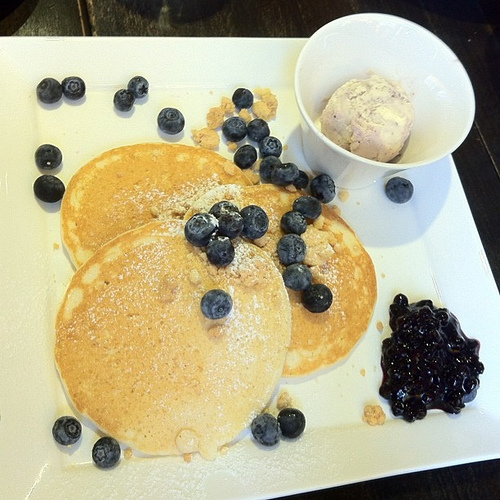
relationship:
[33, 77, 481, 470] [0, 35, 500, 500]
food on dish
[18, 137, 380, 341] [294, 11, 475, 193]
food on bowl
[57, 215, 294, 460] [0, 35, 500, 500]
pancake on dish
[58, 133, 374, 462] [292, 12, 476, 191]
pancakes on dish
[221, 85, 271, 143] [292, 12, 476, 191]
blueberries on dish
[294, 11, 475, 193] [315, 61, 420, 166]
bowl filled butter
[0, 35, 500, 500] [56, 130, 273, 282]
dish filled pancake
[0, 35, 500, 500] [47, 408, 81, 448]
dish filled blueberry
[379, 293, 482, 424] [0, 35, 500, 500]
blueberries on a plate dish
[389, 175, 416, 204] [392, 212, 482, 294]
blueberry on a plate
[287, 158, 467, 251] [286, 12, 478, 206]
shadow on plate